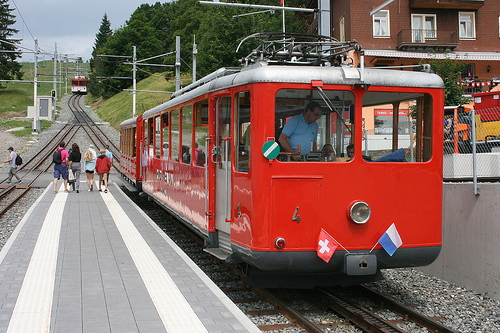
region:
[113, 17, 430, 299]
A red train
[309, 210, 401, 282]
Two flags on the front of the train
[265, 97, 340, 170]
A man on the train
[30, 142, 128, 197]
People walking on the sidewalk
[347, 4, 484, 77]
An apartment behind the train station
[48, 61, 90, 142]
Another train in the distance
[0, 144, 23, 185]
A man crossing the train tracks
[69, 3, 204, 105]
Trees in the background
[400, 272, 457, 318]
Rocks under the track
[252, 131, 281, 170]
A green sign on the front of the train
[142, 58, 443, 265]
front car of a cable car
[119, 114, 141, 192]
back car of a cable car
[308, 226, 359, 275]
a flag on the cable car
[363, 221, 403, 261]
a flag on the cable car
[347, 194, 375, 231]
headlight of the cable car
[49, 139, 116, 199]
five pedestrians near the cable car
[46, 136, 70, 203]
a guy with a backpack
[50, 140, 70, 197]
a man with a pink shirt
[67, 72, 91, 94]
a train in the distance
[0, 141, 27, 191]
a man walking to our left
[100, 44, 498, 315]
red train on tracks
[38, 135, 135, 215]
people walking on side walk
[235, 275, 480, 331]
railway tracks for train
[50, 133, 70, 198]
man wearing a pink shirt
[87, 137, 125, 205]
boy wearing red jacket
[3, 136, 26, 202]
man walking over tracks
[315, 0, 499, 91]
brick building in background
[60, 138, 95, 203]
lady wearing black shirt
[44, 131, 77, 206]
man with black back pack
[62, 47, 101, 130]
train coming in the distance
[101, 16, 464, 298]
A red trolley train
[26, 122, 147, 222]
People walking on the platform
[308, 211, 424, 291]
Two flags on the train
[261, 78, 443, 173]
A glass windshield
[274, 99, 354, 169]
A man inside of the trolley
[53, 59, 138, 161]
A trolley coming down the tracks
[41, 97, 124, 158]
The trolley's tracks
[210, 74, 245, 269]
The trolley's door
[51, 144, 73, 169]
A pink t shirt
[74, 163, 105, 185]
Black shorts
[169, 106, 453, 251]
the train is red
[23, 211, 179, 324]
the pavement is grey and white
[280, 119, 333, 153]
the man has a blue shirt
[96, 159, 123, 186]
his top is red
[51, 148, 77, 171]
his top is orange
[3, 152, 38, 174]
the man has a backpack on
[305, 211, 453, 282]
there are two flags infront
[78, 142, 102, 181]
the woman has blonde hair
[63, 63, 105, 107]
there is train in the background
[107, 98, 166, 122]
the grass is green